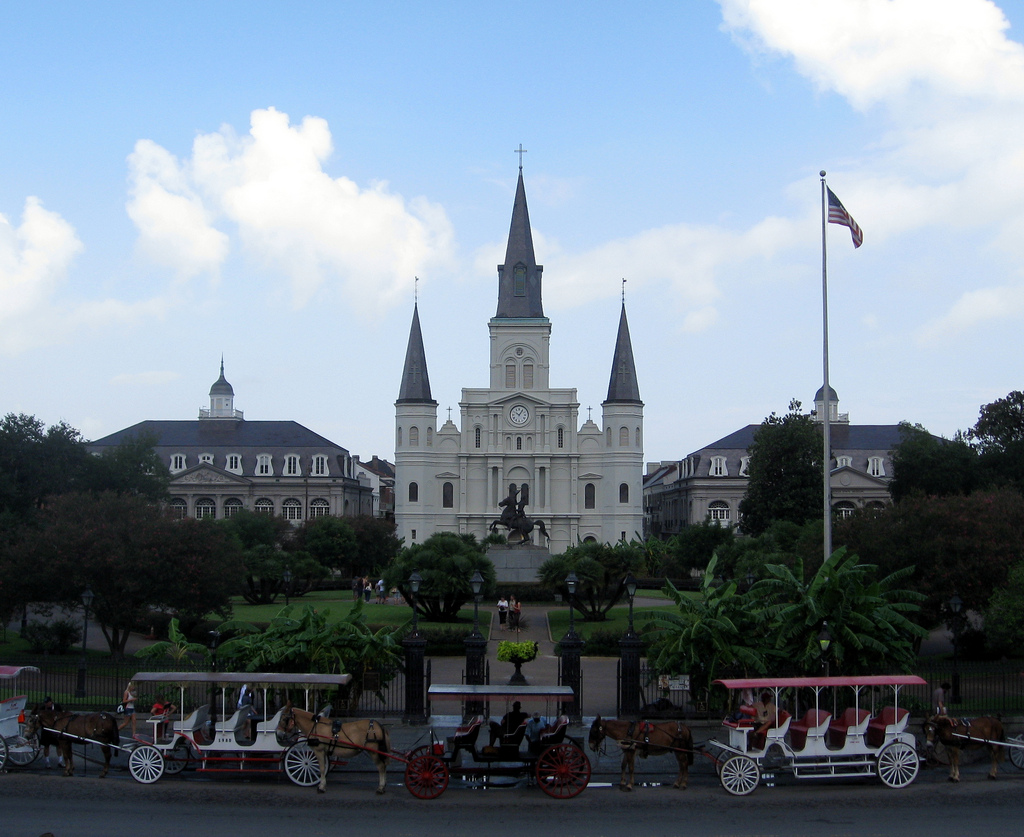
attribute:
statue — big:
[446, 469, 580, 610]